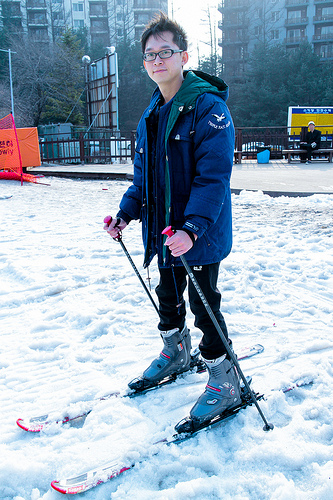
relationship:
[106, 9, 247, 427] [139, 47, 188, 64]
boy wears eyeglasses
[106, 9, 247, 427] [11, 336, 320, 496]
boy wears skis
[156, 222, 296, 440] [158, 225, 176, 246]
stick has handle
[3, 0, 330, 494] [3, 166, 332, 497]
place full of snow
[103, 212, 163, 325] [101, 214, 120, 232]
ski pole with handle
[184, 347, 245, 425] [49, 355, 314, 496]
boot attached to skis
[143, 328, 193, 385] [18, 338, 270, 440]
boot attached to ski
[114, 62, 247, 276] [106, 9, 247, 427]
jacket worn by boy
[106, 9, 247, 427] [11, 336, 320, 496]
boy in skis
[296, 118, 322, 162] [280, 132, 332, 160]
man on bench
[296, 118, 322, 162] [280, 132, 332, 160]
man sitting on bench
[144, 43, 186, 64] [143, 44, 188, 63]
eyeglasses with frame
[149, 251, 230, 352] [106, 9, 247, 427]
pants worn by boy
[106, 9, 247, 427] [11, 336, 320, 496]
boy on skis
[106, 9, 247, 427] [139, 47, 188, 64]
boy wearing eyeglasses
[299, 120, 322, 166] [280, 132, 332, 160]
man on bench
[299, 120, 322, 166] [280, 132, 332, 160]
man sitting on bench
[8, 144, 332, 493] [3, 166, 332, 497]
ground full of snow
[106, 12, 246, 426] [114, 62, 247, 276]
boy in jacket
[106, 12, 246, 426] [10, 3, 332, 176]
boy in city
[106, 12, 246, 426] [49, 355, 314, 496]
boy trying to skis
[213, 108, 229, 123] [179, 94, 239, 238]
bird on arm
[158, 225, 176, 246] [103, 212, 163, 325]
handle on ski pole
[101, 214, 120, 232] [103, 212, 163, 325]
handle on ski pole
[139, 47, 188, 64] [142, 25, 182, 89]
eyeglasses on face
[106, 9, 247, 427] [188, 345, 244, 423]
boy has boot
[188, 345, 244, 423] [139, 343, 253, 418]
boot on feet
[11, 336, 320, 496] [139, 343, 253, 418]
skis on feet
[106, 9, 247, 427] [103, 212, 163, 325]
boy holding ski pole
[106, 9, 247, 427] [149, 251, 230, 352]
boy wearing pants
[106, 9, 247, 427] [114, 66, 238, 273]
boy wearing jacket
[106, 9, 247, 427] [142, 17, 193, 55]
boy has hair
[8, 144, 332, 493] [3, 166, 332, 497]
ground covered in snow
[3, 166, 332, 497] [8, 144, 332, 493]
snow on ground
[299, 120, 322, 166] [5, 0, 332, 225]
man in background